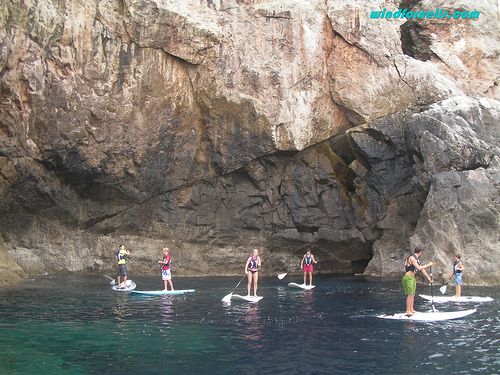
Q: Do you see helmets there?
A: No, there are no helmets.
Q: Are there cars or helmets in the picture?
A: No, there are no helmets or cars.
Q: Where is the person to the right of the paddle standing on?
A: The person is standing on the water.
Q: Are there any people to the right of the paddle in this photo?
A: Yes, there is a person to the right of the paddle.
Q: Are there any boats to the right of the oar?
A: No, there is a person to the right of the oar.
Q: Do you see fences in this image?
A: No, there are no fences.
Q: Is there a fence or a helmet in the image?
A: No, there are no fences or helmets.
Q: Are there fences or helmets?
A: No, there are no fences or helmets.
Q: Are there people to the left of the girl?
A: Yes, there is a person to the left of the girl.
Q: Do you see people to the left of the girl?
A: Yes, there is a person to the left of the girl.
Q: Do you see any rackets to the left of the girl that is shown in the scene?
A: No, there is a person to the left of the girl.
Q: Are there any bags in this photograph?
A: No, there are no bags.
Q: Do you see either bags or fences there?
A: No, there are no bags or fences.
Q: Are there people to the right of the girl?
A: Yes, there is a person to the right of the girl.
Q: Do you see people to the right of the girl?
A: Yes, there is a person to the right of the girl.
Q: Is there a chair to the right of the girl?
A: No, there is a person to the right of the girl.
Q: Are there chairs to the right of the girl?
A: No, there is a person to the right of the girl.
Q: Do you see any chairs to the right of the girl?
A: No, there is a person to the right of the girl.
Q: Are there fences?
A: No, there are no fences.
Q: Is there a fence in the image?
A: No, there are no fences.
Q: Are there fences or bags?
A: No, there are no fences or bags.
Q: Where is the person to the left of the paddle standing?
A: The person is standing on the water.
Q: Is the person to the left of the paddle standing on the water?
A: Yes, the person is standing on the water.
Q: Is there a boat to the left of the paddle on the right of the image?
A: No, there is a person to the left of the oar.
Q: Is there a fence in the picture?
A: No, there are no fences.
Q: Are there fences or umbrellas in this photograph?
A: No, there are no fences or umbrellas.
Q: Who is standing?
A: The people are standing.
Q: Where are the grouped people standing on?
A: The people are standing on the water.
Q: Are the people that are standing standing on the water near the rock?
A: Yes, the people are standing on the water.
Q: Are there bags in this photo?
A: No, there are no bags.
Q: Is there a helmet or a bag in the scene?
A: No, there are no bags or helmets.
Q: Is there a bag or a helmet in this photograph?
A: No, there are no bags or helmets.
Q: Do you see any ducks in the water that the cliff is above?
A: No, there is a person in the water.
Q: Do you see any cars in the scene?
A: No, there are no cars.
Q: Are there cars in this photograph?
A: No, there are no cars.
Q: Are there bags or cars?
A: No, there are no cars or bags.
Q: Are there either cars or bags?
A: No, there are no cars or bags.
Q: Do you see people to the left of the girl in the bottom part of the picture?
A: Yes, there is a person to the left of the girl.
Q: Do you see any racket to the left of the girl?
A: No, there is a person to the left of the girl.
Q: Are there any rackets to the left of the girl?
A: No, there is a person to the left of the girl.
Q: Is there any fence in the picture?
A: No, there are no fences.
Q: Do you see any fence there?
A: No, there are no fences.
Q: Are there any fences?
A: No, there are no fences.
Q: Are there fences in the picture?
A: No, there are no fences.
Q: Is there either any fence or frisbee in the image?
A: No, there are no fences or frisbees.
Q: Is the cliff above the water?
A: Yes, the cliff is above the water.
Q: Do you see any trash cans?
A: No, there are no trash cans.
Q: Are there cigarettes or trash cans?
A: No, there are no trash cans or cigarettes.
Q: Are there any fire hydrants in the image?
A: No, there are no fire hydrants.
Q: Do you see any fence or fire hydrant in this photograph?
A: No, there are no fire hydrants or fences.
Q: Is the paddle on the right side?
A: Yes, the paddle is on the right of the image.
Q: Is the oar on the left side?
A: No, the oar is on the right of the image.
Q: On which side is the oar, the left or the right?
A: The oar is on the right of the image.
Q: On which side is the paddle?
A: The paddle is on the right of the image.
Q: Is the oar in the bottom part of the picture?
A: Yes, the oar is in the bottom of the image.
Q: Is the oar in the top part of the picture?
A: No, the oar is in the bottom of the image.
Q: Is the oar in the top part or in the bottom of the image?
A: The oar is in the bottom of the image.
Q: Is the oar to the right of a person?
A: Yes, the oar is to the right of a person.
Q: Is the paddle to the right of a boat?
A: No, the paddle is to the right of a person.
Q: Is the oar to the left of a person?
A: No, the oar is to the right of a person.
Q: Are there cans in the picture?
A: No, there are no cans.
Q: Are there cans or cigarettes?
A: No, there are no cans or cigarettes.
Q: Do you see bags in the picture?
A: No, there are no bags.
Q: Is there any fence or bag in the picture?
A: No, there are no bags or fences.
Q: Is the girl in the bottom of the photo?
A: Yes, the girl is in the bottom of the image.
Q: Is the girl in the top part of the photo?
A: No, the girl is in the bottom of the image.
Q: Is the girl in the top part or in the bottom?
A: The girl is in the bottom of the image.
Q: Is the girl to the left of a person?
A: No, the girl is to the right of a person.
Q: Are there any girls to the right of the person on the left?
A: Yes, there is a girl to the right of the person.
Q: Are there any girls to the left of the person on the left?
A: No, the girl is to the right of the person.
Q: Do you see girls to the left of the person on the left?
A: No, the girl is to the right of the person.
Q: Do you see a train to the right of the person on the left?
A: No, there is a girl to the right of the person.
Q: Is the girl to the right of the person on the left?
A: Yes, the girl is to the right of the person.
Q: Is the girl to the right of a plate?
A: No, the girl is to the right of the person.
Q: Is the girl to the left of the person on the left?
A: No, the girl is to the right of the person.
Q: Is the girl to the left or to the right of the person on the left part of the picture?
A: The girl is to the right of the person.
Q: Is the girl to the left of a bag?
A: No, the girl is to the left of a person.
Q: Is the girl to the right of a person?
A: No, the girl is to the left of a person.